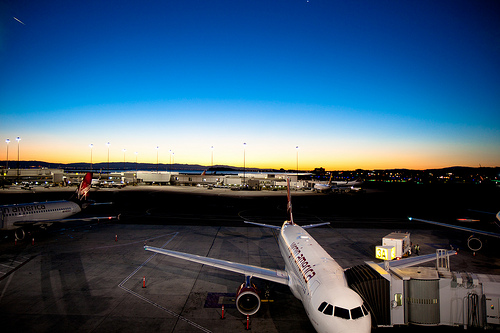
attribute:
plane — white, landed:
[126, 176, 482, 323]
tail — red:
[239, 175, 334, 231]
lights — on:
[7, 143, 319, 169]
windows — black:
[1, 205, 82, 228]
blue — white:
[0, 122, 497, 166]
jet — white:
[141, 177, 464, 331]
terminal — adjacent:
[35, 164, 346, 199]